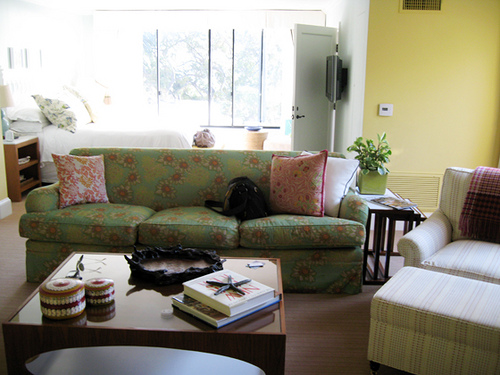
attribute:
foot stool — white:
[366, 262, 496, 372]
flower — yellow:
[282, 262, 327, 291]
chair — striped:
[402, 169, 498, 274]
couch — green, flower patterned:
[15, 138, 373, 294]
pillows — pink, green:
[44, 144, 336, 225]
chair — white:
[392, 158, 499, 288]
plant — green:
[346, 131, 400, 180]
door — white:
[284, 13, 334, 154]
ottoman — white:
[355, 258, 498, 372]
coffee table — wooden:
[6, 244, 295, 373]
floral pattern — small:
[26, 216, 60, 221]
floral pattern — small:
[108, 202, 135, 218]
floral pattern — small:
[232, 167, 261, 192]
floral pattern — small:
[153, 176, 173, 192]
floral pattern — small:
[315, 224, 345, 245]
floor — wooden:
[307, 306, 336, 368]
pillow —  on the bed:
[27, 78, 98, 129]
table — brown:
[6, 224, 312, 373]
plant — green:
[342, 136, 395, 178]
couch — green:
[20, 129, 371, 269]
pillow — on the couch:
[265, 152, 334, 213]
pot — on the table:
[353, 162, 394, 195]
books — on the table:
[169, 269, 274, 326]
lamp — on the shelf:
[0, 80, 18, 139]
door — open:
[281, 13, 342, 154]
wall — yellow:
[398, 67, 476, 146]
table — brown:
[365, 192, 418, 264]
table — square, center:
[17, 229, 294, 373]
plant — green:
[342, 127, 402, 180]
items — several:
[28, 252, 125, 327]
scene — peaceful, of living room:
[0, 14, 493, 373]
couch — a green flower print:
[24, 121, 374, 279]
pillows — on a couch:
[261, 145, 333, 218]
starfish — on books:
[198, 266, 251, 301]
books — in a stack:
[161, 253, 282, 329]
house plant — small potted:
[350, 135, 399, 198]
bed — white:
[5, 58, 236, 146]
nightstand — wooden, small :
[4, 122, 44, 195]